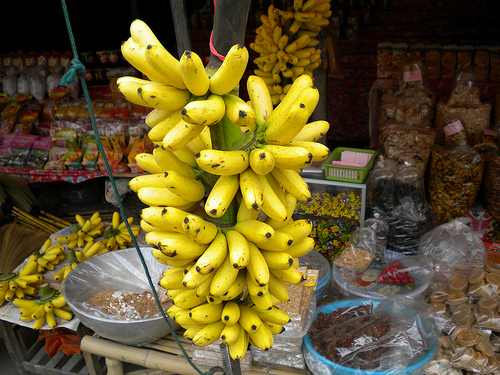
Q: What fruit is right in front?
A: Bananas.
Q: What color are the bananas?
A: Yellow.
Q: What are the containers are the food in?
A: Bowls.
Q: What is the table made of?
A: Bamboo.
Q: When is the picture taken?
A: Daytime.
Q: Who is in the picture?
A: No one.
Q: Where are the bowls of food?
A: On a table.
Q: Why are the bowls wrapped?
A: To protect the food.